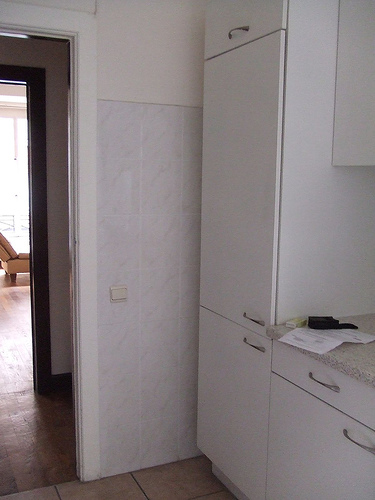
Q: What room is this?
A: It is a kitchen.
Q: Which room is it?
A: It is a kitchen.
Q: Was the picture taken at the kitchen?
A: Yes, it was taken in the kitchen.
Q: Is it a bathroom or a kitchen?
A: It is a kitchen.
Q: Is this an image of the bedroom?
A: No, the picture is showing the kitchen.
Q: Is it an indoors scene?
A: Yes, it is indoors.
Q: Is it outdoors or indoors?
A: It is indoors.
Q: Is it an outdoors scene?
A: No, it is indoors.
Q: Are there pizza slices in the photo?
A: No, there are no pizza slices.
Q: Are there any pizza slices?
A: No, there are no pizza slices.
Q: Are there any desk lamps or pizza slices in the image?
A: No, there are no pizza slices or desk lamps.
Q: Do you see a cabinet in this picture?
A: Yes, there is a cabinet.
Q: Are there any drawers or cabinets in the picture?
A: Yes, there is a cabinet.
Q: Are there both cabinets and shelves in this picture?
A: No, there is a cabinet but no shelves.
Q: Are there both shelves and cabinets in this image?
A: No, there is a cabinet but no shelves.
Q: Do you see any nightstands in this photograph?
A: No, there are no nightstands.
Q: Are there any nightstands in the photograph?
A: No, there are no nightstands.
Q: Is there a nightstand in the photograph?
A: No, there are no nightstands.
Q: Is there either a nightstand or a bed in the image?
A: No, there are no nightstands or beds.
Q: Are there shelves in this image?
A: No, there are no shelves.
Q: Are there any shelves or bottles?
A: No, there are no shelves or bottles.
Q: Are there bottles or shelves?
A: No, there are no shelves or bottles.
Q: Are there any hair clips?
A: No, there are no hair clips.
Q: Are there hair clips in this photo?
A: No, there are no hair clips.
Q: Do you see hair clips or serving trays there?
A: No, there are no hair clips or serving trays.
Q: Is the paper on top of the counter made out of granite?
A: Yes, the paper is on top of the counter.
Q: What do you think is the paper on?
A: The paper is on the counter.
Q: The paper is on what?
A: The paper is on the counter.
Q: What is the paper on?
A: The paper is on the counter.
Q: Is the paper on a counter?
A: Yes, the paper is on a counter.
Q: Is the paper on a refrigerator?
A: No, the paper is on a counter.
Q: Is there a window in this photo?
A: Yes, there is a window.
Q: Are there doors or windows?
A: Yes, there is a window.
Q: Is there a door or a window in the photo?
A: Yes, there is a window.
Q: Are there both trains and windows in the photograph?
A: No, there is a window but no trains.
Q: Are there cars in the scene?
A: No, there are no cars.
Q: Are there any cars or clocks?
A: No, there are no cars or clocks.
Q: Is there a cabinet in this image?
A: Yes, there is a cabinet.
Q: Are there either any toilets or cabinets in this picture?
A: Yes, there is a cabinet.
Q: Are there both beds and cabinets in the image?
A: No, there is a cabinet but no beds.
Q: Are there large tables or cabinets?
A: Yes, there is a large cabinet.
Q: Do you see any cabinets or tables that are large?
A: Yes, the cabinet is large.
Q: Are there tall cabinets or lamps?
A: Yes, there is a tall cabinet.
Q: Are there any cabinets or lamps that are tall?
A: Yes, the cabinet is tall.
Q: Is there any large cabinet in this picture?
A: Yes, there is a large cabinet.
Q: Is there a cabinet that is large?
A: Yes, there is a cabinet that is large.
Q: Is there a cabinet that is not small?
A: Yes, there is a large cabinet.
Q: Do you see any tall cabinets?
A: Yes, there is a tall cabinet.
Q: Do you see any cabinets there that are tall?
A: Yes, there is a cabinet that is tall.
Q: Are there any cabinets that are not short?
A: Yes, there is a tall cabinet.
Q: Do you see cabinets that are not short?
A: Yes, there is a tall cabinet.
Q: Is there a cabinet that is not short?
A: Yes, there is a tall cabinet.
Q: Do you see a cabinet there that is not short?
A: Yes, there is a tall cabinet.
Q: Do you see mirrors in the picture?
A: No, there are no mirrors.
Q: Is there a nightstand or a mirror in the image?
A: No, there are no mirrors or nightstands.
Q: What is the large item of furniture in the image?
A: The piece of furniture is a cabinet.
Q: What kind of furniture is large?
A: The furniture is a cabinet.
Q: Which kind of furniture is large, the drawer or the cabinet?
A: The cabinet is large.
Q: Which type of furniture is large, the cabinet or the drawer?
A: The cabinet is large.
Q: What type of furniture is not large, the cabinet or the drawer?
A: The drawer is not large.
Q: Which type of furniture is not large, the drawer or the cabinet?
A: The drawer is not large.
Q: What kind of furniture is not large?
A: The furniture is a drawer.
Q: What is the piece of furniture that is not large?
A: The piece of furniture is a drawer.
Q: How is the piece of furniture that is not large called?
A: The piece of furniture is a drawer.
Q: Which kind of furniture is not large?
A: The furniture is a drawer.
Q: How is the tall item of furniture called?
A: The piece of furniture is a cabinet.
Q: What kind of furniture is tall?
A: The furniture is a cabinet.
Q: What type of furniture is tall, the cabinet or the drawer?
A: The cabinet is tall.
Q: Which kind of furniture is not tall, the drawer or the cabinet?
A: The drawer is not tall.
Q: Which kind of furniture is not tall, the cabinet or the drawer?
A: The drawer is not tall.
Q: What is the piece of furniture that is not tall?
A: The piece of furniture is a drawer.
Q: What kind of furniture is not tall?
A: The furniture is a drawer.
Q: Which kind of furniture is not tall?
A: The furniture is a drawer.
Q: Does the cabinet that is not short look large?
A: Yes, the cabinet is large.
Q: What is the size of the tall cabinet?
A: The cabinet is large.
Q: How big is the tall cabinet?
A: The cabinet is large.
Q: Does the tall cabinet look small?
A: No, the cabinet is large.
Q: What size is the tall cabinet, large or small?
A: The cabinet is large.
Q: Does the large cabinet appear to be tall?
A: Yes, the cabinet is tall.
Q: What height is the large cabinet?
A: The cabinet is tall.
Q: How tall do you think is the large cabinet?
A: The cabinet is tall.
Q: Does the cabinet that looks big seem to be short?
A: No, the cabinet is tall.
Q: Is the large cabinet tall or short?
A: The cabinet is tall.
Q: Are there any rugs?
A: No, there are no rugs.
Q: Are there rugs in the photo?
A: No, there are no rugs.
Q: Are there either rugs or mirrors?
A: No, there are no rugs or mirrors.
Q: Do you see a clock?
A: No, there are no clocks.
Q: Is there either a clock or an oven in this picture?
A: No, there are no clocks or ovens.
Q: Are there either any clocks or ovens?
A: No, there are no clocks or ovens.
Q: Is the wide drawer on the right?
A: Yes, the drawer is on the right of the image.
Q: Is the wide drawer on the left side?
A: No, the drawer is on the right of the image.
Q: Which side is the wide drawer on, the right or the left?
A: The drawer is on the right of the image.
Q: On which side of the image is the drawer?
A: The drawer is on the right of the image.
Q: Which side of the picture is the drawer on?
A: The drawer is on the right of the image.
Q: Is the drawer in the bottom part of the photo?
A: Yes, the drawer is in the bottom of the image.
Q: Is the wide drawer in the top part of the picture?
A: No, the drawer is in the bottom of the image.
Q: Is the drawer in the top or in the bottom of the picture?
A: The drawer is in the bottom of the image.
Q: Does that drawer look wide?
A: Yes, the drawer is wide.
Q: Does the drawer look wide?
A: Yes, the drawer is wide.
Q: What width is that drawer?
A: The drawer is wide.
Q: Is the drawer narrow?
A: No, the drawer is wide.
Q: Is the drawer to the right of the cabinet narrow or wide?
A: The drawer is wide.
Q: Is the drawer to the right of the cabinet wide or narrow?
A: The drawer is wide.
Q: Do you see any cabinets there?
A: Yes, there is a cabinet.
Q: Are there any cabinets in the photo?
A: Yes, there is a cabinet.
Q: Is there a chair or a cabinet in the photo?
A: Yes, there is a cabinet.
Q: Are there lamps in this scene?
A: No, there are no lamps.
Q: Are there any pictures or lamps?
A: No, there are no lamps or pictures.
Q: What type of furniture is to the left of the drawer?
A: The piece of furniture is a cabinet.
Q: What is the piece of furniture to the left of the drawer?
A: The piece of furniture is a cabinet.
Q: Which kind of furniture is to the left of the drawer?
A: The piece of furniture is a cabinet.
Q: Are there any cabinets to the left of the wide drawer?
A: Yes, there is a cabinet to the left of the drawer.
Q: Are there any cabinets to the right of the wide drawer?
A: No, the cabinet is to the left of the drawer.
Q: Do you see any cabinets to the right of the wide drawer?
A: No, the cabinet is to the left of the drawer.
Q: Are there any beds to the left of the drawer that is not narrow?
A: No, there is a cabinet to the left of the drawer.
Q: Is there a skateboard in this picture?
A: No, there are no skateboards.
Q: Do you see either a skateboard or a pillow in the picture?
A: No, there are no skateboards or pillows.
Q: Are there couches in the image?
A: Yes, there is a couch.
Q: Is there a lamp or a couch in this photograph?
A: Yes, there is a couch.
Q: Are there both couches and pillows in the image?
A: No, there is a couch but no pillows.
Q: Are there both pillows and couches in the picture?
A: No, there is a couch but no pillows.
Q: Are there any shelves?
A: No, there are no shelves.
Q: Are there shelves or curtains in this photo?
A: No, there are no shelves or curtains.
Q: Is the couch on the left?
A: Yes, the couch is on the left of the image.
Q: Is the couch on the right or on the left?
A: The couch is on the left of the image.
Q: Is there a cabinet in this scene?
A: Yes, there is a cabinet.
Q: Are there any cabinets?
A: Yes, there is a cabinet.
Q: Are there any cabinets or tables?
A: Yes, there is a cabinet.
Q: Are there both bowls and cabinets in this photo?
A: No, there is a cabinet but no bowls.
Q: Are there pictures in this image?
A: No, there are no pictures.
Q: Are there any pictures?
A: No, there are no pictures.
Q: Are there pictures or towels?
A: No, there are no pictures or towels.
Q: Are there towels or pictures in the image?
A: No, there are no pictures or towels.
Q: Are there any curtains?
A: No, there are no curtains.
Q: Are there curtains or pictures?
A: No, there are no curtains or pictures.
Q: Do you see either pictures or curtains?
A: No, there are no curtains or pictures.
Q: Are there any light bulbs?
A: No, there are no light bulbs.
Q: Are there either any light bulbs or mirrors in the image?
A: No, there are no light bulbs or mirrors.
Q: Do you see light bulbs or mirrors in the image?
A: No, there are no light bulbs or mirrors.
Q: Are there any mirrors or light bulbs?
A: No, there are no light bulbs or mirrors.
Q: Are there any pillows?
A: No, there are no pillows.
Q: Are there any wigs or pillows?
A: No, there are no pillows or wigs.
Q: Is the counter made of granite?
A: Yes, the counter is made of granite.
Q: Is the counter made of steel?
A: No, the counter is made of granite.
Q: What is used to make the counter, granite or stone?
A: The counter is made of granite.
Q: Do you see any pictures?
A: No, there are no pictures.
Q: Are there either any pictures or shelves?
A: No, there are no pictures or shelves.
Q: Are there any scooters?
A: No, there are no scooters.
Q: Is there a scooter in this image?
A: No, there are no scooters.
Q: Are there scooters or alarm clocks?
A: No, there are no scooters or alarm clocks.